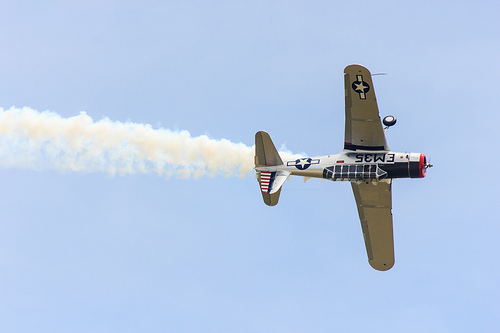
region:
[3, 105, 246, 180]
white trail of exhaust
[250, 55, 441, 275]
airplane flying upside down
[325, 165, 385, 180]
windows above plane's cockpit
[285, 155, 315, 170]
white and blue star on body of plane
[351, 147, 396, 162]
identification on body of plane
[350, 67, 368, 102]
blue and white star design on plane's wing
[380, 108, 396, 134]
wheel of plane above wing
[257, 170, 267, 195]
red and white stripes on tail of plane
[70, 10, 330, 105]
sky appears pale blue and cloudless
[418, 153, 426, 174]
red paint on front of plane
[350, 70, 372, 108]
Blue and White star logo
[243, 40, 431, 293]
brown, white, blue, and red airplane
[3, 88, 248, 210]
white puffy smoke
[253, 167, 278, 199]
red white and blue logo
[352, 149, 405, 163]
white paint with blue letters and numbers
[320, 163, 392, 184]
cockpit window with silver metal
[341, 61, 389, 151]
Light Brown wing with star logo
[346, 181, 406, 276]
Light Brown Wing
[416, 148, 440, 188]
Nose of plane with red trim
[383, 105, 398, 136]
white and black rubber tire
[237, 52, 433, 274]
Plane flying in the sky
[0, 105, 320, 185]
Water vapor from plane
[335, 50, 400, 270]
Wings of plane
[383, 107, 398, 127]
Wheel of plane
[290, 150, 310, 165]
White star on a blue circle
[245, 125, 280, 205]
Vertical stabilizer of blue and tan plane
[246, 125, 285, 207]
Horizontal stabilizer of plane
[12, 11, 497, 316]
Plane flying in a blue sky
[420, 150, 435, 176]
Propeller in front of plane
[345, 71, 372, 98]
White star in a wing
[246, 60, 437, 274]
Small plane in the air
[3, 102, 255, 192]
Smoke in the sky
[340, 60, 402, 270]
Wings of plane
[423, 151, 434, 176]
Propeller of plane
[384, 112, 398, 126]
Black tire of plane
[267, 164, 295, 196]
Vertical stabilizer of plane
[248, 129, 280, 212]
Horizontal stabilized of plane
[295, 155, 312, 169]
White star in a blue circle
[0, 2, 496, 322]
Plane flying in the sky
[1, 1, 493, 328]
Smoky plane in the sky